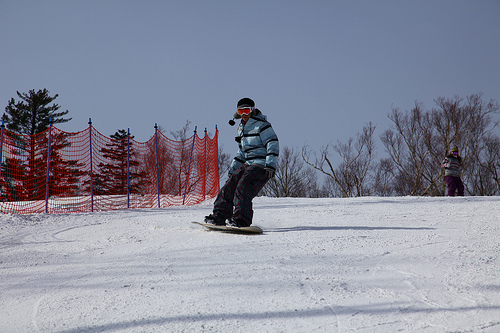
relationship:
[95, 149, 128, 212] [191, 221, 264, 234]
fence near snowboard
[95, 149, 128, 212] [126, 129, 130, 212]
fence has post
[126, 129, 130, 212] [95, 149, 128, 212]
post supports fence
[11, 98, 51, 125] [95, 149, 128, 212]
tree behind fence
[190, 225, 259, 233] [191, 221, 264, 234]
snowboard under snowboard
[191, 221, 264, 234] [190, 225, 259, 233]
snowboard has snowboard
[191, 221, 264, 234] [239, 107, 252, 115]
snowboard wearing goggles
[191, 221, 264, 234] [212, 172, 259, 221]
snowboard wearing pants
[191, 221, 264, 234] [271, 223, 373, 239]
snowboard casts shadow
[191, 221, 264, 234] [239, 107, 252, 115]
snowboard wears goggles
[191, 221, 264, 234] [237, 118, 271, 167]
snowboard wearing jacket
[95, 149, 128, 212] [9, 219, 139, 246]
fence on hill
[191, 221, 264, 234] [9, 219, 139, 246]
snowboard on hill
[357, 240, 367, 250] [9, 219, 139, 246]
snow on hill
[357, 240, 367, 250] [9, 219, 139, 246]
snow covered hill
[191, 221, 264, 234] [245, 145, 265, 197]
snowboard wearing clothing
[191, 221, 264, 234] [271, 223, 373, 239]
snowboard has shadow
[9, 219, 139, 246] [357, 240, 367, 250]
hill has snow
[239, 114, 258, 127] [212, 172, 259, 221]
girl wearing pants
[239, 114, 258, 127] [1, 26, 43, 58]
girl facing left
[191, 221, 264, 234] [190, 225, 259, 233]
snowboard riding snowboard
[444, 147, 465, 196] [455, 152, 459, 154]
person wearing goggles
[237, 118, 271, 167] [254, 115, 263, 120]
jacket has hood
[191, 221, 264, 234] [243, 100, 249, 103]
snowboard wearing hat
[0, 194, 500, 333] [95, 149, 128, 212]
snow on fence